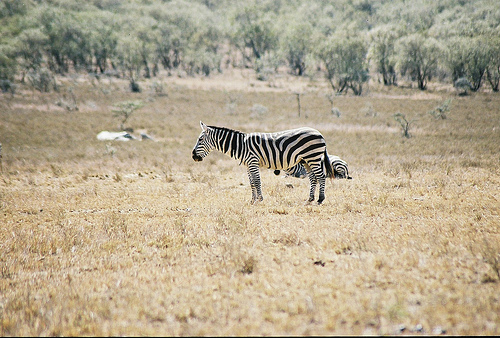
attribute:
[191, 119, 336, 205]
zebra — standing, striped, laying, black, wild, white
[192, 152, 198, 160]
snout — black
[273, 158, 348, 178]
zebra — lying, laying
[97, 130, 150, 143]
rock — lit, large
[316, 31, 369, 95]
tree — dark, far, tiny, growing, small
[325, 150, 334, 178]
tail — black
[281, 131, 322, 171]
stripe — white, black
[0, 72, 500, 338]
field — brown